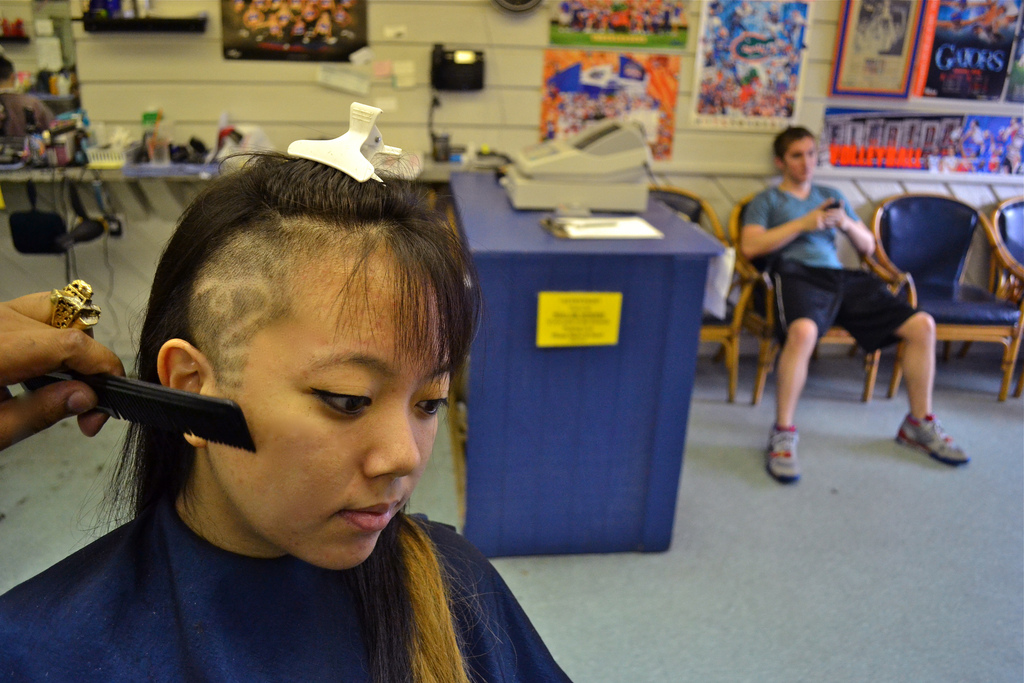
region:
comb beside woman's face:
[51, 340, 260, 462]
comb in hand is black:
[47, 353, 262, 474]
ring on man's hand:
[47, 264, 108, 338]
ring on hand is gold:
[38, 271, 121, 351]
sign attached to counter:
[528, 276, 628, 362]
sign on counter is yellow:
[529, 284, 628, 357]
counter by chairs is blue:
[434, 137, 710, 574]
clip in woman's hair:
[276, 82, 401, 204]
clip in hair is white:
[278, 85, 409, 197]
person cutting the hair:
[21, 121, 562, 681]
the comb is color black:
[73, 346, 260, 465]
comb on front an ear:
[91, 333, 269, 485]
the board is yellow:
[524, 271, 633, 358]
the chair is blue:
[869, 170, 1018, 405]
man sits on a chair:
[720, 109, 978, 502]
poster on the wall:
[528, 11, 706, 173]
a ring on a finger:
[12, 245, 115, 359]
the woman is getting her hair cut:
[5, 134, 546, 651]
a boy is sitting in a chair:
[671, 20, 981, 518]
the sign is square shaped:
[463, 248, 648, 384]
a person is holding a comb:
[0, 247, 288, 507]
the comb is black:
[13, 321, 317, 503]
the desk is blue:
[411, 96, 734, 575]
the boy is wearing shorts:
[732, 226, 957, 381]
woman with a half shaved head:
[180, 211, 299, 361]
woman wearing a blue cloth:
[28, 502, 446, 659]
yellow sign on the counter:
[520, 281, 634, 349]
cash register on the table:
[495, 114, 651, 213]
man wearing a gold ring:
[40, 263, 102, 331]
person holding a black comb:
[65, 350, 255, 443]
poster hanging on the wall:
[537, 50, 675, 159]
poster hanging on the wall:
[701, 0, 800, 128]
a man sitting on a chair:
[752, 132, 974, 481]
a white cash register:
[511, 119, 649, 212]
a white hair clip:
[294, 101, 393, 179]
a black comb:
[81, 370, 260, 444]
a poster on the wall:
[531, 47, 674, 147]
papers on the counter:
[537, 203, 665, 251]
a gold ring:
[51, 275, 103, 336]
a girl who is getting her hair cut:
[98, 158, 523, 680]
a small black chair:
[19, 205, 121, 241]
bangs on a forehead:
[323, 244, 479, 374]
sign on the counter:
[525, 265, 631, 370]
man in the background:
[712, 133, 975, 489]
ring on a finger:
[34, 262, 107, 345]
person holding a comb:
[1, 287, 258, 496]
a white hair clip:
[287, 72, 417, 203]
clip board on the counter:
[528, 195, 678, 246]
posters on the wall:
[502, 0, 1019, 163]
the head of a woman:
[171, 160, 475, 606]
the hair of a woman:
[321, 195, 478, 341]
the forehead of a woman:
[302, 245, 439, 367]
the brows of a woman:
[343, 340, 457, 394]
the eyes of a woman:
[280, 372, 446, 442]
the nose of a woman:
[348, 420, 434, 496]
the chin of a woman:
[315, 523, 385, 580]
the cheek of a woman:
[238, 442, 352, 528]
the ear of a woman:
[141, 324, 241, 441]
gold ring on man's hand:
[49, 279, 103, 331]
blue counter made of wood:
[453, 171, 723, 549]